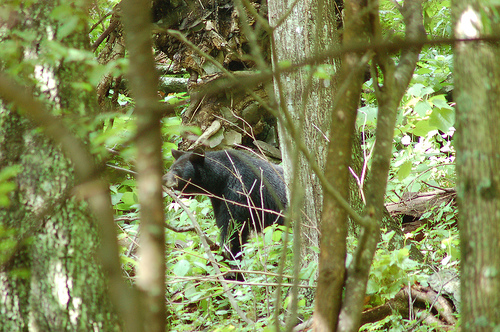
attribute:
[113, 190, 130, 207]
leaves — green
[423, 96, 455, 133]
leaves — green , large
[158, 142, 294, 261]
mammal — omnivorous 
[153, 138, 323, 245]
bear — black 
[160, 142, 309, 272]
bear — alert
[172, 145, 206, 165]
ears — alert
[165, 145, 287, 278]
bear — hungry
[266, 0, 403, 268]
trunk — tree trunk , smooth , barked 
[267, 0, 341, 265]
lichen — green 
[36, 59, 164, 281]
area — wooded area 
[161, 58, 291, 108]
twig — BLURRED